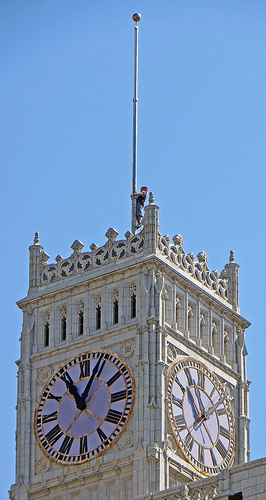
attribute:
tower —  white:
[8, 191, 252, 497]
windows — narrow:
[35, 279, 156, 355]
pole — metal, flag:
[129, 16, 141, 193]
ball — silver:
[130, 11, 144, 21]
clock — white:
[20, 339, 128, 461]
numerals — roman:
[173, 371, 194, 385]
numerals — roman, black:
[188, 378, 228, 404]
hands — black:
[184, 372, 225, 423]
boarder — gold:
[175, 358, 188, 363]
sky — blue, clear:
[153, 96, 203, 135]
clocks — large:
[37, 363, 216, 420]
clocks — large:
[48, 348, 225, 423]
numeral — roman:
[58, 352, 107, 378]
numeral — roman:
[98, 352, 119, 372]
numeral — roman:
[103, 367, 124, 383]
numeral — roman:
[107, 381, 160, 409]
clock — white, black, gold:
[32, 349, 134, 465]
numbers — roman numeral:
[170, 367, 232, 466]